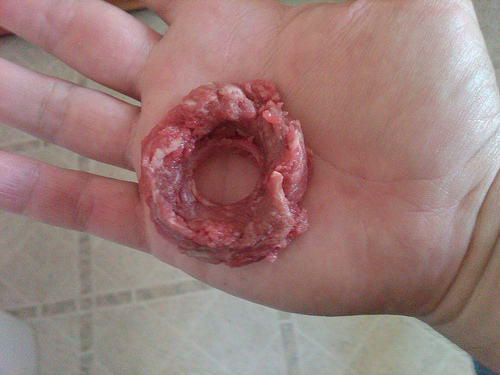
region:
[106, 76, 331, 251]
Person holding meat shaped like a dough nut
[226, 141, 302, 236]
Person holding meat shaped like a dough nut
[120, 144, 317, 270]
Person holding meat shaped like a dough nut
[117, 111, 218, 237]
Person holding meat shaped like a dough nut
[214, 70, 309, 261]
Person holding meat shaped like a dough nut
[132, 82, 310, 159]
Person holding meat shaped like a dough nut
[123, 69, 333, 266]
pastry in the hand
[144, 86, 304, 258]
a circular piece of meat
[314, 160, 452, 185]
arched line on palm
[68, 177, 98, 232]
lines in fingers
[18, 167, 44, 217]
lines in fingers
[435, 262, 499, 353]
the persons wrist in left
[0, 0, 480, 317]
the persons hand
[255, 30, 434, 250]
the palm of persons hand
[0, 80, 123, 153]
a persons finger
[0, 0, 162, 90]
a persons finger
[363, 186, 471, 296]
light flesh color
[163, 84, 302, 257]
Meat on the hand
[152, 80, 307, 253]
Round meat ball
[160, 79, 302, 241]
Meat in the photo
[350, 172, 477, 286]
A hand in the photo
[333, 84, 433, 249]
An open arm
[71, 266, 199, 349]
A floor with tile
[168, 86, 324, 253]
A red meat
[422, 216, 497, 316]
A person in the photo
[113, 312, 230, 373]
Tiles in the photo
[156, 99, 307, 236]
A meat in the open arm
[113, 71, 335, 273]
this is a roll of meat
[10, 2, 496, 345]
the hand of a person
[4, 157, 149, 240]
the finger of a person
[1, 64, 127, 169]
the finger of a person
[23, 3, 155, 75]
the finger of a person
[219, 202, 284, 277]
a piece of beef meat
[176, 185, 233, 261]
a piece of beef meat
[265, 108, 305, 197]
a piece of beef meat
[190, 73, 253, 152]
a piece of beef meat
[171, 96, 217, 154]
a piece of beef meat